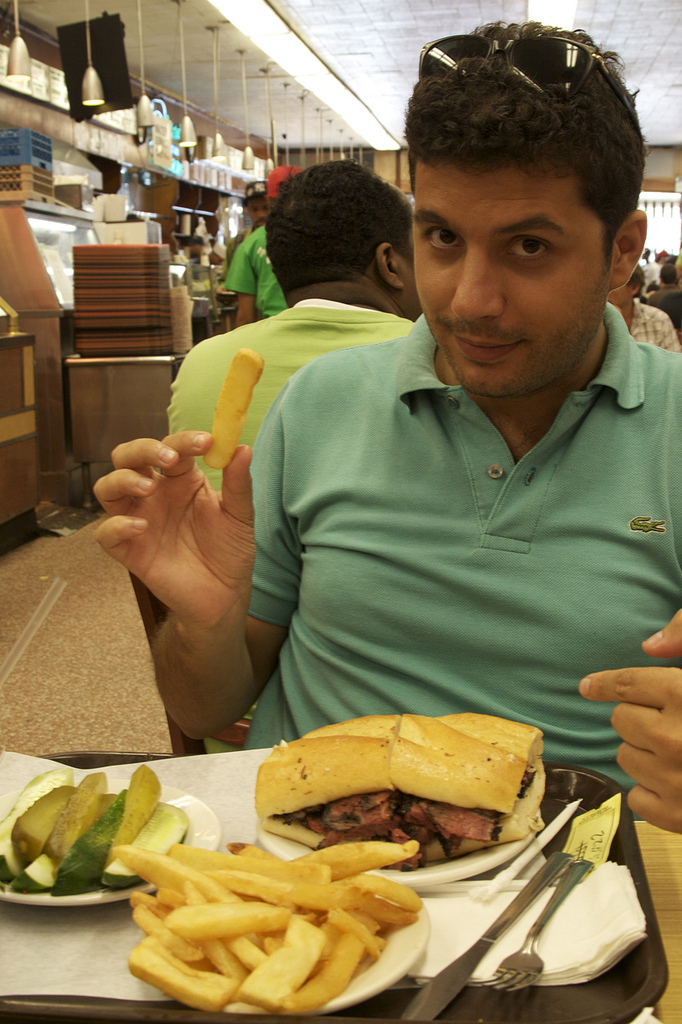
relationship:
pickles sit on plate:
[0, 764, 187, 896] [17, 755, 235, 932]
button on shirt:
[481, 447, 505, 486] [265, 308, 674, 755]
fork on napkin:
[482, 860, 594, 992] [411, 857, 644, 985]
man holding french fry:
[93, 21, 682, 840] [198, 353, 269, 472]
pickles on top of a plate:
[2, 766, 184, 882] [184, 789, 223, 847]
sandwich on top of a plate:
[257, 709, 548, 849] [419, 837, 535, 899]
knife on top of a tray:
[407, 853, 571, 1020] [468, 983, 661, 1018]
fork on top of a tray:
[494, 858, 595, 1000] [468, 983, 661, 1018]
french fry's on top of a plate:
[116, 839, 413, 1012] [340, 908, 433, 1013]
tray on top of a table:
[0, 751, 668, 1023] [634, 819, 660, 884]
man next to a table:
[93, 21, 682, 840] [636, 818, 660, 857]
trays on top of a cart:
[71, 240, 180, 356] [66, 355, 175, 439]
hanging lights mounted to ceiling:
[133, 4, 157, 137] [230, 1, 393, 141]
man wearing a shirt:
[93, 21, 682, 840] [259, 300, 647, 734]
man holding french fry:
[93, 21, 682, 840] [209, 344, 267, 470]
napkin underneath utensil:
[407, 860, 647, 984] [492, 856, 596, 1004]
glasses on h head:
[410, 25, 596, 89] [388, 17, 633, 398]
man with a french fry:
[83, 37, 680, 852] [198, 353, 269, 473]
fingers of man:
[571, 590, 680, 833] [93, 21, 682, 840]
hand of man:
[90, 422, 251, 640] [93, 21, 682, 840]